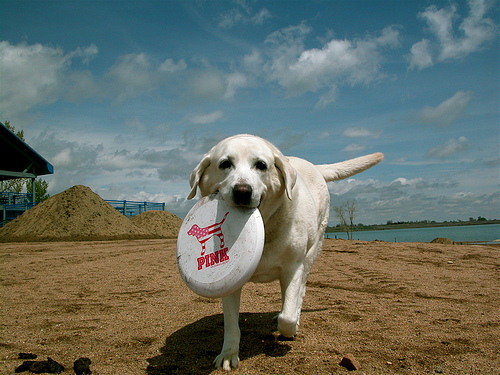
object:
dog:
[186, 132, 384, 372]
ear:
[275, 145, 298, 201]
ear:
[185, 150, 210, 200]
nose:
[232, 183, 253, 196]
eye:
[219, 159, 233, 169]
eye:
[255, 160, 267, 170]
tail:
[315, 152, 384, 182]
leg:
[278, 266, 307, 338]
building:
[0, 120, 54, 220]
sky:
[0, 0, 499, 221]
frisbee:
[175, 196, 265, 300]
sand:
[0, 184, 156, 243]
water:
[414, 228, 499, 237]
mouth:
[217, 189, 264, 208]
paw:
[212, 354, 240, 372]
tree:
[332, 197, 360, 241]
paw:
[277, 316, 298, 338]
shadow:
[143, 306, 329, 373]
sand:
[1, 238, 500, 375]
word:
[196, 247, 229, 270]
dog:
[186, 211, 229, 256]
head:
[187, 133, 298, 208]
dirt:
[130, 210, 184, 239]